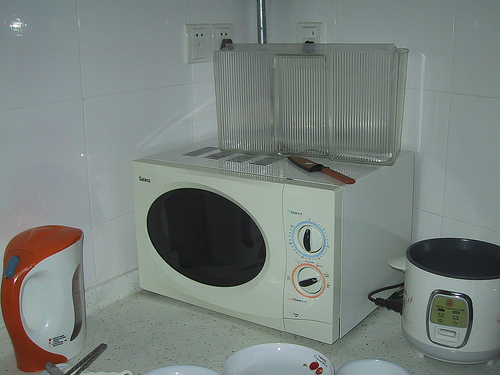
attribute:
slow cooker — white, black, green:
[402, 237, 499, 366]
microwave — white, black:
[129, 134, 415, 345]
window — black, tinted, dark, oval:
[145, 184, 268, 287]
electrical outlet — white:
[183, 23, 212, 65]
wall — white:
[0, 0, 499, 328]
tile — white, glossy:
[77, 84, 195, 226]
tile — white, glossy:
[73, 0, 202, 101]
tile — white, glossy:
[0, 0, 96, 113]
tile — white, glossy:
[0, 96, 93, 247]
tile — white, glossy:
[328, 0, 461, 96]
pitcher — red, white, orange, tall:
[2, 225, 88, 372]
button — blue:
[3, 253, 20, 278]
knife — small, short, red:
[285, 152, 355, 186]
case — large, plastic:
[211, 39, 408, 165]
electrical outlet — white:
[213, 19, 237, 62]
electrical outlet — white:
[297, 23, 324, 61]